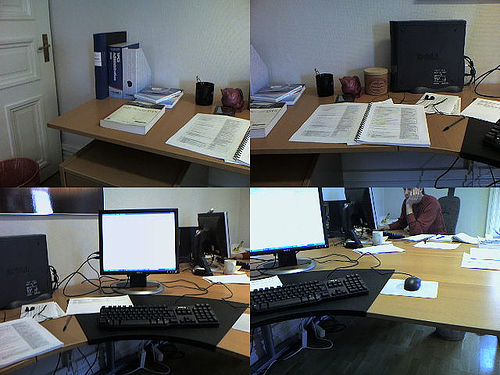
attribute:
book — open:
[292, 101, 431, 146]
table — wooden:
[250, 86, 500, 166]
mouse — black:
[405, 276, 420, 290]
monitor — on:
[98, 209, 180, 276]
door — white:
[2, 1, 66, 182]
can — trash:
[2, 157, 42, 187]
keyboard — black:
[99, 304, 218, 326]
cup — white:
[373, 231, 383, 244]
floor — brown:
[253, 313, 499, 374]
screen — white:
[250, 188, 326, 253]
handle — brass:
[38, 33, 51, 63]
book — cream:
[102, 101, 165, 134]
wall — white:
[49, 0, 250, 188]